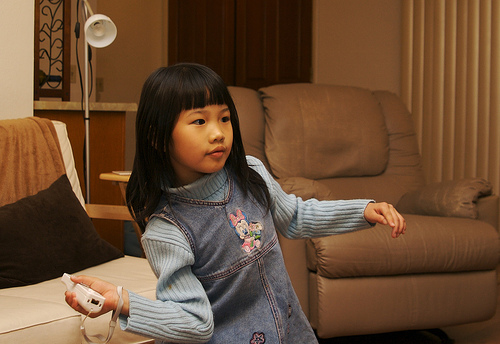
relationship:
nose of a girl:
[208, 126, 225, 144] [64, 63, 405, 344]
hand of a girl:
[364, 201, 408, 238] [64, 63, 405, 344]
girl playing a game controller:
[64, 63, 405, 344] [59, 272, 110, 316]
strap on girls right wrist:
[78, 282, 124, 342] [111, 279, 127, 313]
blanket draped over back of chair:
[0, 115, 127, 292] [0, 117, 164, 344]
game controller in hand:
[59, 272, 110, 316] [63, 274, 113, 319]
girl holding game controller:
[64, 63, 405, 344] [59, 272, 110, 316]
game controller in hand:
[59, 272, 110, 316] [65, 276, 122, 317]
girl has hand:
[64, 63, 405, 344] [65, 276, 122, 317]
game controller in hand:
[59, 272, 110, 316] [66, 275, 117, 316]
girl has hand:
[64, 63, 405, 344] [66, 275, 117, 316]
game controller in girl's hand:
[59, 272, 110, 316] [71, 271, 121, 306]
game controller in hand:
[59, 272, 110, 316] [46, 217, 203, 341]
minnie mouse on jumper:
[226, 206, 262, 254] [150, 188, 328, 342]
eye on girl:
[189, 116, 206, 126] [64, 63, 405, 344]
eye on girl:
[219, 114, 231, 123] [64, 63, 405, 344]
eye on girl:
[219, 114, 231, 124] [64, 63, 405, 344]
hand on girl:
[358, 197, 408, 242] [64, 63, 405, 344]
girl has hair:
[117, 63, 314, 268] [126, 61, 273, 231]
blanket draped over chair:
[0, 115, 127, 292] [0, 117, 158, 341]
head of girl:
[124, 67, 274, 164] [64, 63, 405, 344]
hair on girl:
[126, 61, 273, 231] [64, 63, 405, 344]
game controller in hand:
[59, 272, 110, 316] [64, 270, 125, 326]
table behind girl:
[97, 167, 132, 199] [64, 63, 405, 344]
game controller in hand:
[59, 272, 110, 316] [60, 267, 231, 339]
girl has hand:
[64, 63, 405, 344] [60, 267, 231, 339]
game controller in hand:
[59, 272, 110, 316] [89, 283, 122, 305]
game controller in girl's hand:
[59, 272, 110, 316] [63, 274, 120, 317]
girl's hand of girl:
[63, 274, 120, 317] [64, 63, 405, 344]